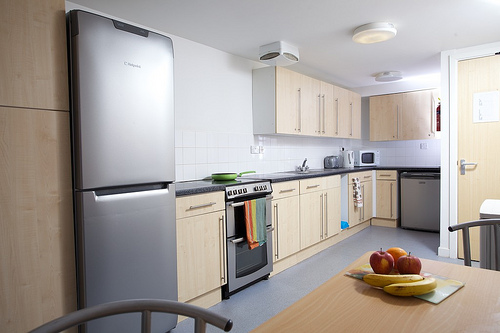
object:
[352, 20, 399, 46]
light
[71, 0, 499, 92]
ceiling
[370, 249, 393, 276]
red apple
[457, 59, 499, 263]
door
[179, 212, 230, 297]
cabinet door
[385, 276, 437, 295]
banana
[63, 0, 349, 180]
wall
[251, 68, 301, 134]
cabinets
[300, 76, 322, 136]
cabinets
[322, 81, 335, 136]
cabinets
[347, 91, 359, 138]
cabinets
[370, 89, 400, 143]
cabinets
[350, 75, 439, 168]
wall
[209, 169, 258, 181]
pan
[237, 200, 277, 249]
towel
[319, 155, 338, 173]
toaster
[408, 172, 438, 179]
handle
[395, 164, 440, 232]
dishwasher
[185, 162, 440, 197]
counter top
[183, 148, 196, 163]
tile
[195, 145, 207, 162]
tile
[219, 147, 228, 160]
tile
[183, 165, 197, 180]
tile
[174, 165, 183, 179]
tile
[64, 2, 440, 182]
wall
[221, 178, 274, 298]
stove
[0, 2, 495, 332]
kitchen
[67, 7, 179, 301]
desserts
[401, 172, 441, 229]
dishwasher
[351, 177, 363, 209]
towel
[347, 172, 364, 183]
drawer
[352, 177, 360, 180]
handle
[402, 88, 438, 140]
cabinets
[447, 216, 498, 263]
chair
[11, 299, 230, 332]
chair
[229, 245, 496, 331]
table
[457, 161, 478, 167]
handle